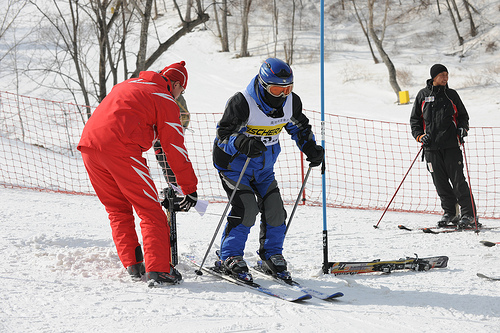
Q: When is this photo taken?
A: Winter.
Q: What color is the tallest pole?
A: Blue.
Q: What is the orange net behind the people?
A: Fence.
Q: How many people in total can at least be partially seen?
A: Four.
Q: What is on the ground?
A: Snow.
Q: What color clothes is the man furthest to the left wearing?
A: Red.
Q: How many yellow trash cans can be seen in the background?
A: One.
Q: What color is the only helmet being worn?
A: Blue.